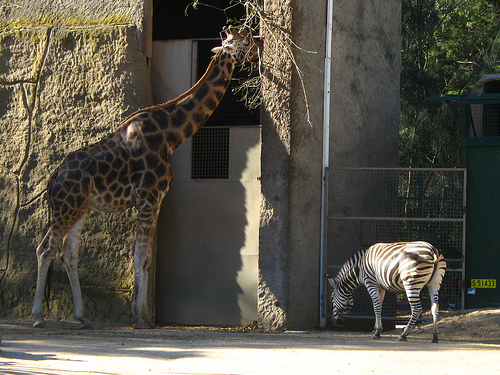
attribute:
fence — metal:
[327, 167, 464, 249]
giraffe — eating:
[33, 25, 245, 328]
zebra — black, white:
[317, 204, 478, 346]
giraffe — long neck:
[18, 54, 308, 250]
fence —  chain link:
[321, 157, 498, 328]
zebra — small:
[325, 234, 467, 342]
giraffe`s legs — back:
[30, 187, 91, 329]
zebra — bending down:
[327, 238, 461, 353]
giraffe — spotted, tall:
[21, 28, 269, 331]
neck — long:
[153, 55, 233, 160]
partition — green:
[456, 97, 498, 298]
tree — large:
[396, 4, 449, 224]